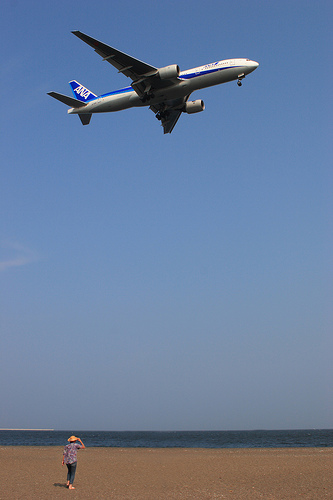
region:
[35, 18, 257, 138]
plane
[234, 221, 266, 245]
white clouds in blue sky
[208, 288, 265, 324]
white clouds in blue sky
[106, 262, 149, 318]
white clouds in blue sky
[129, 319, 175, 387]
white clouds in blue sky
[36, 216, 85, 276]
white clouds in blue sky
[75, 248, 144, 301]
white clouds in blue sky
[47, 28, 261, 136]
a airplane flying in the air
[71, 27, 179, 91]
the wing of a plane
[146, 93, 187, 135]
the wing of a plane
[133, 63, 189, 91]
the engine of a plane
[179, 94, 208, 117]
the engine of a plane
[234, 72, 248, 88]
the landing gear of a plane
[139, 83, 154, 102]
the landing gear of a plane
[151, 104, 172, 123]
the landing gear of a plane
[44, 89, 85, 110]
the tail wing of a plane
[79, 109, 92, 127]
the tail wing of a plane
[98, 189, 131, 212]
white clouds in blue sky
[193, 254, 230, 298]
white clouds in blue sky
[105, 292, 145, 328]
white clouds in blue sky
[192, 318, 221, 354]
white clouds in blue sky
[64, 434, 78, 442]
a beige hat with a brim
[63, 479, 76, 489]
bare feet in the sand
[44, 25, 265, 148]
an airplane in the sky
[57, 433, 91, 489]
a person walking on the beach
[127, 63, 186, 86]
a jet engine on an airplane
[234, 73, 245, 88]
the front landing gear on an airplane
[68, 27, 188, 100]
an aircraft wing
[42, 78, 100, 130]
an aircraft tail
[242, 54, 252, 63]
windows in the cockpit of an airplane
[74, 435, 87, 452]
the arm of a person on the beach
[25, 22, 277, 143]
Plane flying in midair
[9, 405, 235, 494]
Women standing on beach in jeans and decorated top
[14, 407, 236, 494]
Women holding her hat while standing on beach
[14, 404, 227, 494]
Women holding her straw hat in the middle of sandy beach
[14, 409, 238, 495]
Women walking toward ocean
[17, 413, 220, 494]
Women walking toward beach while holding her hat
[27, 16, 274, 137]
Airplane in flight in the middle of sky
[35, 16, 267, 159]
Airplane flying overhead during the afternoon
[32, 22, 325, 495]
Plane flying over women's head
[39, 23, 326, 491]
Plane flying over women wearing a hat and blue jeans